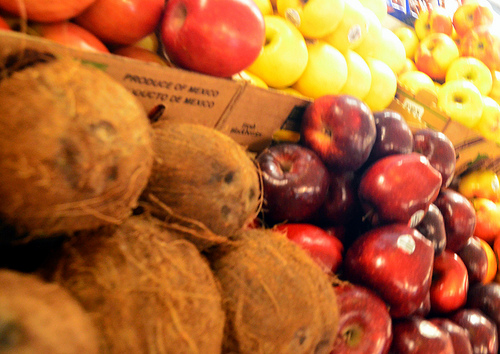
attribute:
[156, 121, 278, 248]
coconut shell — brown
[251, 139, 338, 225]
apple — overripe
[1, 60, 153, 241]
coconut — brown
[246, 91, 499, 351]
apples — red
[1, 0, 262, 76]
apples — red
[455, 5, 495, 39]
apple — yellow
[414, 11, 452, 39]
apple — yellow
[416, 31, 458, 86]
apple — yellow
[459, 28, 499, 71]
apple — yellow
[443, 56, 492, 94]
apple — yellow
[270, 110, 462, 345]
fruit — sold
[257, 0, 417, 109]
apples — yellow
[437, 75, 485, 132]
apples — sour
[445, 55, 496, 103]
apples — sour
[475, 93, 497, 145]
apples — sour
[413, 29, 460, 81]
apples — sour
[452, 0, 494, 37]
apples — sour